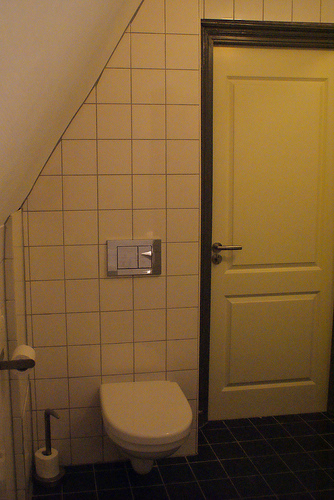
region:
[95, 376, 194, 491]
a white toilet with no tank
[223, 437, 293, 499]
bathroom floor tile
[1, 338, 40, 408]
a toilet paper roll dispenser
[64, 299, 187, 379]
white bathroom wall tile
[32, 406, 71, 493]
extra roll of toilet paper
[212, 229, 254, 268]
metal door handle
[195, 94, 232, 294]
bathroom door jam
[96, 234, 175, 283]
metal control box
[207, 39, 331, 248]
white bathroom door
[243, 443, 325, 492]
white grout on floor tile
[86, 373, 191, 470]
The toilet is white.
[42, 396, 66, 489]
The toilet paper holder has one role.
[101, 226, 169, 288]
The light switch is silver.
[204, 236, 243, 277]
The handle is silver.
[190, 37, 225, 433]
The boarder is brown.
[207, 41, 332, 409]
The door is white.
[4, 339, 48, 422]
The toilet paper dispenser is brown.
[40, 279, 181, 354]
The tile is white.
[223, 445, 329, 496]
The tile is brown.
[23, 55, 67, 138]
The ceiling is white.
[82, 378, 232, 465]
The toilet is white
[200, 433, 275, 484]
The floor is dark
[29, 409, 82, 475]
There is one roll of toilet paper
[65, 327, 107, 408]
The wall is tiled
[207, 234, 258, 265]
The door handle is metal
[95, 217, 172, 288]
This item is silver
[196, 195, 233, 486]
The door is shut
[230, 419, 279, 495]
The floor is tiled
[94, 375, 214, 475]
The toilet is closed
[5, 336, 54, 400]
The toilet paper is white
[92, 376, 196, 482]
porcelain toilet that is attached to the wall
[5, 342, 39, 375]
toilet paper holder on the side of the wall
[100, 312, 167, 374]
four square white tiles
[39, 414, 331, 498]
black tile on the floor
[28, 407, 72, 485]
toilet paper holder holding one roll of toilet paper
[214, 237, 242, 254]
long, silver door handle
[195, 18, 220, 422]
dark wooden door frame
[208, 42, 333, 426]
door with a yellowish tint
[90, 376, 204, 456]
toilet lit is down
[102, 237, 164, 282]
shiny silver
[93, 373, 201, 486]
modern white toilet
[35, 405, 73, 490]
toilet paper roll holder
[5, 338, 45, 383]
toilet paper roll holder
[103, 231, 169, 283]
silver rectangle on the wall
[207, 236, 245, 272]
door handle and lock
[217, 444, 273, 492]
brown tile on the bathroom floor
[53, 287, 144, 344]
cream colored tile on the bathroom wall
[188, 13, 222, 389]
brown trim around the bathroom door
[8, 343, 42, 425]
roll of white toilet paper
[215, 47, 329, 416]
yellowish two panel door